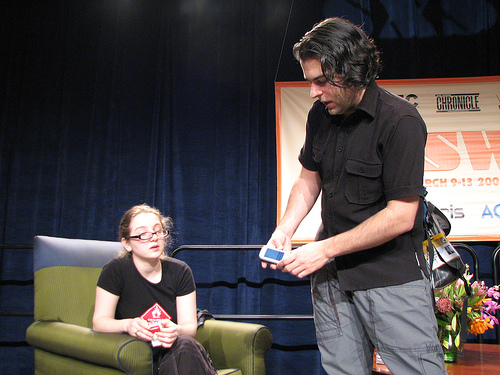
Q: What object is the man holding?
A: A cell phone.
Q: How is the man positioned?
A: Standing to the left of the girl on the chair.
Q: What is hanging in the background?
A: A large sign with an orange border.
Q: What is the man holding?
A: A cell phone.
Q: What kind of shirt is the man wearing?
A: A black shirt with the sleeves rolled up.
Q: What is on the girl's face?
A: Glasses.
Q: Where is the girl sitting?
A: In a chair.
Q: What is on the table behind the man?
A: Flowers.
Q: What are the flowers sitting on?
A: A table.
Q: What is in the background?
A: A large dark blue curtain.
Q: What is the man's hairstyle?
A: Medium length and wavy.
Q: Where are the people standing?
A: On a stage.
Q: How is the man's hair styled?
A: Wavy.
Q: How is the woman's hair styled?
A: Pulled back.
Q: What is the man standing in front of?
A: A sign.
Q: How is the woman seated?
A: Cross-legged.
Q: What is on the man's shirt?
A: A pocket.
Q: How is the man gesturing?
A: At his phone.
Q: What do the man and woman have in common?
A: Black shirts.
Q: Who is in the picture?
A: A man and woman.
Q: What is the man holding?
A: A phone.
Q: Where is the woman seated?
A: On a green armchair.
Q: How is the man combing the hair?
A: To the sides.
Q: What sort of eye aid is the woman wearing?
A: Glasses.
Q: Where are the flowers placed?
A: On the wooden table.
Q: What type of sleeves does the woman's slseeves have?
A: Short sleeves.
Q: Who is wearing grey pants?
A: The man.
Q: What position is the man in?
A: Standing.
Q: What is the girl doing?
A: Sitting down.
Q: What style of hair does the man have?
A: The man has long hair.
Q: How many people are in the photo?
A: Two.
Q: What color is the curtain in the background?
A: Blue.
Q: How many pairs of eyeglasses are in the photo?
A: One.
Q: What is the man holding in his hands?
A: Electronic device.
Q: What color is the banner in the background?
A: Orange, black and white.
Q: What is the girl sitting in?
A: Chair.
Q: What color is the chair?
A: Grey and green.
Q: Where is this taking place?
A: At a lecture.